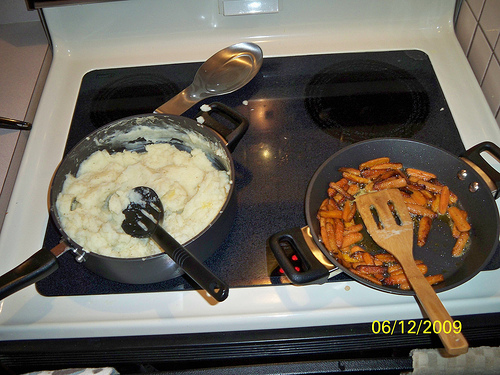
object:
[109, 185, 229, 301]
plastic spoon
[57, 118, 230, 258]
potato